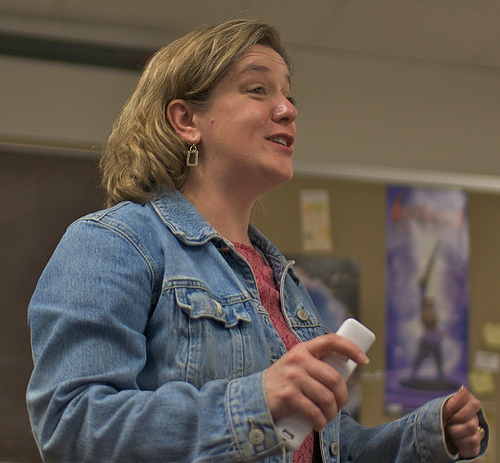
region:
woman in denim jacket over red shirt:
[23, 15, 484, 452]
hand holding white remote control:
[272, 295, 373, 450]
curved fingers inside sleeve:
[437, 375, 487, 455]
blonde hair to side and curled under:
[95, 11, 297, 206]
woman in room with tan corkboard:
[20, 15, 495, 456]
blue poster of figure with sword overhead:
[380, 175, 485, 407]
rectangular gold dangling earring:
[165, 95, 200, 170]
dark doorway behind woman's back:
[2, 125, 122, 455]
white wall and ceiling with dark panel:
[0, 5, 490, 180]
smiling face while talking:
[223, 41, 303, 178]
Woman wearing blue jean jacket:
[25, 8, 438, 448]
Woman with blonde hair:
[85, 18, 337, 229]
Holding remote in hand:
[217, 285, 396, 461]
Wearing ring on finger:
[390, 365, 498, 457]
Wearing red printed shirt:
[135, 188, 396, 459]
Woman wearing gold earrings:
[97, 9, 332, 254]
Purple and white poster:
[350, 117, 496, 447]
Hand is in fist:
[375, 351, 495, 460]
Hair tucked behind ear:
[83, 15, 354, 262]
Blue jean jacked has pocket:
[29, 178, 469, 459]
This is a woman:
[12, 8, 490, 452]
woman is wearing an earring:
[140, 83, 264, 203]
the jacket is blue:
[60, 165, 393, 461]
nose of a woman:
[268, 95, 302, 124]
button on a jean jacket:
[245, 426, 268, 447]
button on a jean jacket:
[210, 294, 222, 314]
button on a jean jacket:
[294, 305, 309, 322]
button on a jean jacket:
[327, 435, 344, 457]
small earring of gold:
[185, 138, 202, 171]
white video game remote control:
[262, 306, 377, 461]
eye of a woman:
[244, 77, 271, 98]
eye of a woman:
[284, 87, 296, 109]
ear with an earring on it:
[155, 95, 209, 172]